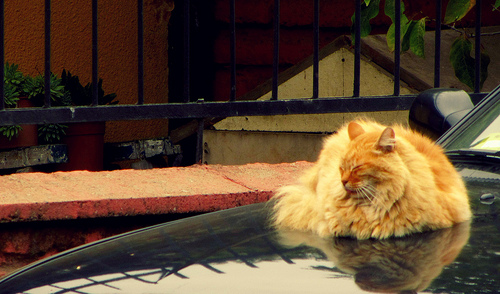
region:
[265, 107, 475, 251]
reclined fluffy orange cat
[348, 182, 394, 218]
whiskers on cat face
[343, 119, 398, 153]
ears on cat head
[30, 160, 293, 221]
flat top of red wall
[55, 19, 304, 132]
poles on metal railing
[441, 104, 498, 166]
corner of car windshield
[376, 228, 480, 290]
refelction of cat on car hood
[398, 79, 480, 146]
side view mirror on car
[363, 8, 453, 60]
green leaves behind fence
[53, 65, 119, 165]
plant in red pot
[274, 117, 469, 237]
long-haired orange cat asleep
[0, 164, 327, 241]
red brick wall ledge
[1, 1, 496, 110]
black barred iron fence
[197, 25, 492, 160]
tan stucco shed with roof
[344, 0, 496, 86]
green plant with large leaves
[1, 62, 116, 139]
spiky green plant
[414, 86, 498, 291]
side-view mirror on black car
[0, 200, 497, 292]
hood of black car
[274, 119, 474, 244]
large sleeping orange cat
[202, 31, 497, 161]
beige garage with brown top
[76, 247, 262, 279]
reflection in hood of car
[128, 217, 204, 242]
black edge of car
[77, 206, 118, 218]
small white line on red brick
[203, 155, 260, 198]
large crack in red brick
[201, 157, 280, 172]
rough edges of red brick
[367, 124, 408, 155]
perked up ears of cat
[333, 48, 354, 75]
small house on roof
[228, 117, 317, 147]
yellow color on wall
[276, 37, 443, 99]
black lines on yellow paint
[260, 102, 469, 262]
large tan and orange color on cat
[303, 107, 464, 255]
an orange cat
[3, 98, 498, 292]
a black car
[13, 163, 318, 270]
a red brick wall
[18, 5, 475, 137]
an iron fence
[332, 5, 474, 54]
leaves hanging behind the fence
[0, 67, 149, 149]
some shrubs behind the fence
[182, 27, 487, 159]
a small shed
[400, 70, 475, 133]
a side mirror of the car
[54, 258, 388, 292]
the reflection of the sky on the car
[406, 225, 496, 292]
the reflection of a tree on the car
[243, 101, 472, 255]
a orange furry cat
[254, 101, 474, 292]
a cat sitting on a car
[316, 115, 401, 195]
a cat with closed eyes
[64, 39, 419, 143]
a black iron fence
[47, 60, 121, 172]
a plant and pot sitting next to building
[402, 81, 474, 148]
rear view mirror on a car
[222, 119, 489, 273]
a cat sleeping on a car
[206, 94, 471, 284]
a cat sitting on a car hood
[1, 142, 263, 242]
a red concrete wall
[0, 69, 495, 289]
a car parked next to a wall